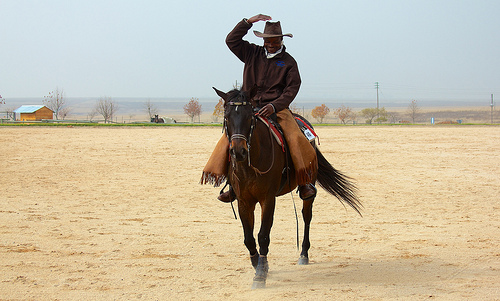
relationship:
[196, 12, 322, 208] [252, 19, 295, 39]
cowboy holding cowboy hat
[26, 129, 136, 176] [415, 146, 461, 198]
field full of sand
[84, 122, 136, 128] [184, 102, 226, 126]
grass has trees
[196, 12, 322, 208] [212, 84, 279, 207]
cowboy riding horse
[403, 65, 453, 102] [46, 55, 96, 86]
dust in air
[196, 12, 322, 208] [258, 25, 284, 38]
cowboy wearing a cowboy hat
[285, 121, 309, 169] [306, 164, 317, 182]
chaps have fringe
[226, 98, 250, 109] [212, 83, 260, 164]
reins on horse head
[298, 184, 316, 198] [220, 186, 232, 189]
foot in stirrup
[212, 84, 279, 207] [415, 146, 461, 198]
horse in sand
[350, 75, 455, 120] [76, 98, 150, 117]
horizon in distance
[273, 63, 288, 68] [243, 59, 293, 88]
writing on jacket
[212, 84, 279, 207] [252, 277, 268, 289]
horse has a hoof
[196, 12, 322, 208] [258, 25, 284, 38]
cowboy holding cowboy hat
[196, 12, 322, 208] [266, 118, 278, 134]
cowboy sitting on top of th saddle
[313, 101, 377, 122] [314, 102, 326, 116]
trees turning orange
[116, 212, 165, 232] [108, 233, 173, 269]
footprints in terrain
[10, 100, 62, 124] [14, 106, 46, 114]
building with roof